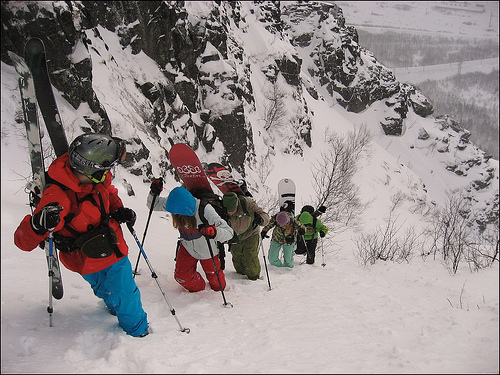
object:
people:
[220, 191, 269, 281]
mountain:
[2, 1, 500, 375]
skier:
[146, 176, 233, 293]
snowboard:
[168, 142, 239, 246]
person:
[15, 133, 149, 339]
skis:
[7, 50, 64, 300]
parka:
[13, 151, 128, 276]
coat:
[296, 211, 328, 240]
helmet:
[67, 132, 127, 176]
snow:
[2, 1, 500, 374]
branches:
[375, 198, 399, 259]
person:
[259, 210, 304, 268]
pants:
[268, 238, 295, 267]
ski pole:
[124, 219, 189, 333]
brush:
[307, 140, 345, 264]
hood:
[165, 187, 197, 217]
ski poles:
[199, 225, 230, 306]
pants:
[80, 256, 150, 337]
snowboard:
[278, 177, 296, 219]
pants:
[296, 238, 318, 265]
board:
[204, 162, 246, 196]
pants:
[172, 240, 227, 293]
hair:
[171, 214, 198, 231]